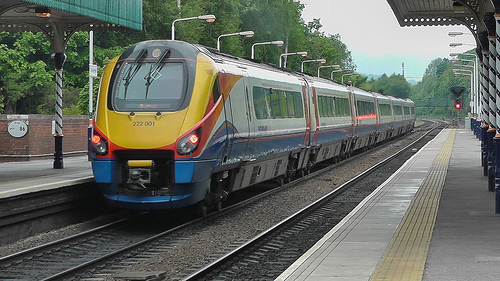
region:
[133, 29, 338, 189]
this is a train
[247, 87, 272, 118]
this is the window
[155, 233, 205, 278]
this is the railway line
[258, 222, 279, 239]
this is a metal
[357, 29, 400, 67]
this is the sky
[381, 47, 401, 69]
the sky is blue in color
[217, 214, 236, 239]
these are small rocks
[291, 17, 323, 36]
this is a tree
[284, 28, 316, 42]
the leaves are green in color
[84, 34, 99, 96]
this is a pole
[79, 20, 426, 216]
A train in the photo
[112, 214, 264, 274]
A railway track in the photo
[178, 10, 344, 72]
Street lights in the photo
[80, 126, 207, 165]
Headlights in the photo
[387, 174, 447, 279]
A side walk in the photo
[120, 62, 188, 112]
A windscreen in the photo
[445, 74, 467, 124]
A traffic sign in the photo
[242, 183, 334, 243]
Track ballast in the photo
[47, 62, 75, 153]
A pole in the photo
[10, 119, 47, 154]
A wall in the photo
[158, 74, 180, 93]
part of a window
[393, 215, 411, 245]
part of a floor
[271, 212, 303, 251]
edge of a rail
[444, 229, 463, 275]
part of a floor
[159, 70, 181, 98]
part of a win dow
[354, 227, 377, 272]
part of a floor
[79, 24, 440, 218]
this is a train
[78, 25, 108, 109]
this is a light pole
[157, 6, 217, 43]
this is a light pole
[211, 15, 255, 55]
this is a light pole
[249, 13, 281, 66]
this is a light pole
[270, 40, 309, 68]
this is a light pole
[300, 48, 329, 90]
this is a light pole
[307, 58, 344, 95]
this is a light pole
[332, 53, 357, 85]
this is a light pole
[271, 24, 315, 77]
this is a light pole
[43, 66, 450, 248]
This is a long train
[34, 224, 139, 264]
These are train tracks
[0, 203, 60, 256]
The tracks are black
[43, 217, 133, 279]
The tracks are metal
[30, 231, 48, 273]
The tracks are steel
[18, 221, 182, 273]
The tracks have rust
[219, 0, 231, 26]
The trees are old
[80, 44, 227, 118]
This is a window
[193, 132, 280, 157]
The light is red